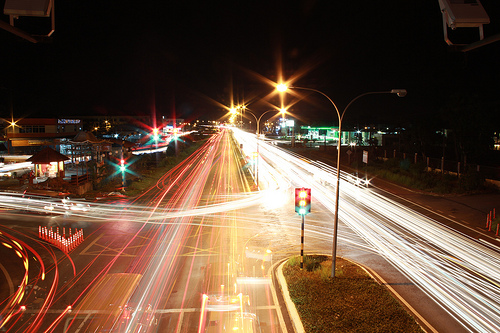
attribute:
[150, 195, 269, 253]
lights — moving, blurred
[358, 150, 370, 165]
sign — green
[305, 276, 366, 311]
grass — green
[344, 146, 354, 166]
pole — metal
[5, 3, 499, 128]
sky — black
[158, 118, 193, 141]
sign — red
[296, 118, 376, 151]
gas station — green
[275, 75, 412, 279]
street light — burned out, metal, lit, street light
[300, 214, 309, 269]
pole — black, yellow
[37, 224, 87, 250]
street cones — orange, white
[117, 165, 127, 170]
light — glowing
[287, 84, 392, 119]
poles — curved